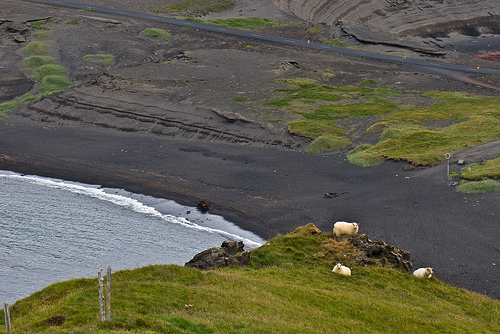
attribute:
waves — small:
[92, 184, 160, 226]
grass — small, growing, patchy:
[383, 106, 473, 151]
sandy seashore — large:
[1, 0, 499, 292]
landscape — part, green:
[260, 235, 382, 315]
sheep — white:
[330, 218, 364, 240]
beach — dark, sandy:
[13, 20, 456, 270]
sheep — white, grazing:
[333, 220, 359, 238]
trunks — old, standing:
[1, 256, 118, 331]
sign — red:
[444, 144, 456, 176]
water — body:
[15, 193, 167, 290]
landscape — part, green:
[127, 278, 447, 333]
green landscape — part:
[0, 233, 499, 332]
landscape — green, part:
[261, 264, 326, 301]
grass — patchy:
[271, 75, 498, 168]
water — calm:
[0, 170, 263, 307]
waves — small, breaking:
[1, 171, 261, 249]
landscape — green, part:
[106, 177, 411, 330]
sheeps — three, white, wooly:
[316, 210, 440, 295]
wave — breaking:
[2, 170, 268, 253]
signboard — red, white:
[443, 153, 450, 159]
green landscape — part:
[185, 282, 228, 326]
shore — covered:
[1, 155, 268, 256]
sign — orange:
[471, 62, 484, 75]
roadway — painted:
[326, 37, 388, 67]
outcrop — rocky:
[186, 237, 253, 274]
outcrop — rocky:
[348, 230, 416, 272]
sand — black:
[3, 0, 496, 299]